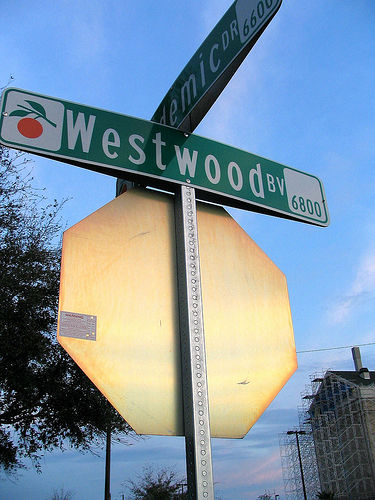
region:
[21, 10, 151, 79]
this is the sky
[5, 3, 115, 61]
the sky is blue in color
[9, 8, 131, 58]
the sky is clear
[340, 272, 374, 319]
the sky has some clouds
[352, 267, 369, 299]
the cloud is white in color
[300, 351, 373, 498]
this is a building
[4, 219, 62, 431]
this is a tree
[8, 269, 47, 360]
the leaves are green in color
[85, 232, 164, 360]
this is a signboard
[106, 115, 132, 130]
the signboard is green in color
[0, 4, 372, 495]
the photo was taken outdoors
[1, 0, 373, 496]
the sky is blue in color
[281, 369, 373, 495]
the building has scaffoling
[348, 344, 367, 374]
the building has a chimney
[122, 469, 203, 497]
a tree is in the background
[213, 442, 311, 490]
the cloud is reddish in color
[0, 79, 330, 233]
a sign is on a pole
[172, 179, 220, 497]
the pole is made of steel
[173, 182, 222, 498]
the pole is grey in color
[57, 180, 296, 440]
a traffic sign is on the pole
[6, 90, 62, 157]
orange symbol on street sign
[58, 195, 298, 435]
back side of stop sign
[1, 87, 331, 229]
street name is westwood bv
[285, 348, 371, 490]
structure in lower right of photo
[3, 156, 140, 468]
tall tree in background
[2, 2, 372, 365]
blue and clear sky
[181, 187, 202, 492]
metal pole holding sign up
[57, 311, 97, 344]
label on back of sign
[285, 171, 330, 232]
street number is 6800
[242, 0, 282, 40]
street number is 6600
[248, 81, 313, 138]
blue and white skies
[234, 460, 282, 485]
streak of white clouds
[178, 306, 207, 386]
line of plugs in sign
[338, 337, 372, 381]
large silver stack on top of building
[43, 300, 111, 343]
tan sign on gold street sign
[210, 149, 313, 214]
green and white street sign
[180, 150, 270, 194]
white words on the sign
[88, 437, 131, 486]
large trunk of tree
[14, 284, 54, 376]
large green tree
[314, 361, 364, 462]
tall building under construction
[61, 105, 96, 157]
white letter "W" on street sign.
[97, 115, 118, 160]
white letter "e" on street sign.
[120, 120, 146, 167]
white letter "s" on street sign.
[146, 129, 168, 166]
white letter "t" on street sign.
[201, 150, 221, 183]
white letter "o" on street sign.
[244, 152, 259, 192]
white letter "d" on street sign.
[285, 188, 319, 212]
green number "6800" on street sign.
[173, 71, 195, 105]
white letter "m" on street sign.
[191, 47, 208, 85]
white letter "i" on street sign.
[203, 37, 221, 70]
white letter "c" on street sign.